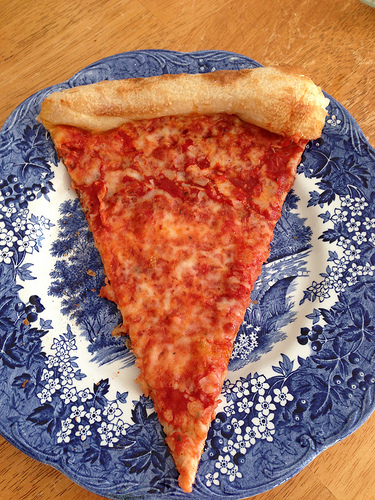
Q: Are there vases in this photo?
A: No, there are no vases.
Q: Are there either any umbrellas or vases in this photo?
A: No, there are no vases or umbrellas.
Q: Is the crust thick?
A: Yes, the crust is thick.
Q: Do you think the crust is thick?
A: Yes, the crust is thick.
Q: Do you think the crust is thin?
A: No, the crust is thick.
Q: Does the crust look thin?
A: No, the crust is thick.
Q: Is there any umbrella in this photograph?
A: No, there are no umbrellas.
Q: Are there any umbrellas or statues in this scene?
A: No, there are no umbrellas or statues.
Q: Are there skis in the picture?
A: No, there are no skis.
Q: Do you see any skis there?
A: No, there are no skis.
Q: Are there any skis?
A: No, there are no skis.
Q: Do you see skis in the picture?
A: No, there are no skis.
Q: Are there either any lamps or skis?
A: No, there are no skis or lamps.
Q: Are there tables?
A: Yes, there is a table.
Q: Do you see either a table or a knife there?
A: Yes, there is a table.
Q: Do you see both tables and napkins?
A: No, there is a table but no napkins.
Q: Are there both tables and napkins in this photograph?
A: No, there is a table but no napkins.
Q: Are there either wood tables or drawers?
A: Yes, there is a wood table.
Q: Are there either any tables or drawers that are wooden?
A: Yes, the table is wooden.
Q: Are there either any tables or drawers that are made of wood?
A: Yes, the table is made of wood.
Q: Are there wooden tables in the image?
A: Yes, there is a wood table.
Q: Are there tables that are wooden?
A: Yes, there is a table that is wooden.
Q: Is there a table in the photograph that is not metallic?
A: Yes, there is a wooden table.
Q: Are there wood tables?
A: Yes, there is a table that is made of wood.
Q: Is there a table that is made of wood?
A: Yes, there is a table that is made of wood.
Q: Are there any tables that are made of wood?
A: Yes, there is a table that is made of wood.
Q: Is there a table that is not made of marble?
A: Yes, there is a table that is made of wood.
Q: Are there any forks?
A: No, there are no forks.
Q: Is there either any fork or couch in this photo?
A: No, there are no forks or couches.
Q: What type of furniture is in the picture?
A: The furniture is a table.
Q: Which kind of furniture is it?
A: The piece of furniture is a table.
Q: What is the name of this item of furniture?
A: This is a table.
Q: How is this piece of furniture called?
A: This is a table.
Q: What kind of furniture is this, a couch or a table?
A: This is a table.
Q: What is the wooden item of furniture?
A: The piece of furniture is a table.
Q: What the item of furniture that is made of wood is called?
A: The piece of furniture is a table.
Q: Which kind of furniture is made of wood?
A: The furniture is a table.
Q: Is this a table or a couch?
A: This is a table.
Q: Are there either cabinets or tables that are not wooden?
A: No, there is a table but it is wooden.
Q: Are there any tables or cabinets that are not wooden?
A: No, there is a table but it is wooden.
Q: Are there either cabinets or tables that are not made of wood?
A: No, there is a table but it is made of wood.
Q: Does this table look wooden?
A: Yes, the table is wooden.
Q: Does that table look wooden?
A: Yes, the table is wooden.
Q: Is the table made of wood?
A: Yes, the table is made of wood.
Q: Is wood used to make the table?
A: Yes, the table is made of wood.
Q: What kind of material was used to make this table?
A: The table is made of wood.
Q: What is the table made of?
A: The table is made of wood.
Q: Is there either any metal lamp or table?
A: No, there is a table but it is wooden.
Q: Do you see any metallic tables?
A: No, there is a table but it is wooden.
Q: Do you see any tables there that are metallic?
A: No, there is a table but it is wooden.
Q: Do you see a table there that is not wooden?
A: No, there is a table but it is wooden.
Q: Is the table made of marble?
A: No, the table is made of wood.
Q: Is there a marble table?
A: No, there is a table but it is made of wood.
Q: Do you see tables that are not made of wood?
A: No, there is a table but it is made of wood.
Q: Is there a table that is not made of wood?
A: No, there is a table but it is made of wood.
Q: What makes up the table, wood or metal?
A: The table is made of wood.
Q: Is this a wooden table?
A: Yes, this is a wooden table.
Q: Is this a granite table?
A: No, this is a wooden table.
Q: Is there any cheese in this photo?
A: Yes, there is cheese.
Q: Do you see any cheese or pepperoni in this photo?
A: Yes, there is cheese.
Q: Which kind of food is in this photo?
A: The food is cheese.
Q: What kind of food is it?
A: The food is cheese.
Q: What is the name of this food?
A: This is cheese.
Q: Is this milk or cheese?
A: This is cheese.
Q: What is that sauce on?
A: The sauce is on the cheese.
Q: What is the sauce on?
A: The sauce is on the cheese.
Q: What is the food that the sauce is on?
A: The food is cheese.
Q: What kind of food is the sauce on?
A: The sauce is on the cheese.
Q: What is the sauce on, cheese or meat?
A: The sauce is on cheese.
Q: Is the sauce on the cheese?
A: Yes, the sauce is on the cheese.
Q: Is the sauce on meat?
A: No, the sauce is on the cheese.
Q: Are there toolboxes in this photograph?
A: No, there are no toolboxes.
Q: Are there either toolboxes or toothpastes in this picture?
A: No, there are no toolboxes or toothpastes.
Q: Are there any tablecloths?
A: No, there are no tablecloths.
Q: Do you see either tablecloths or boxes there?
A: No, there are no tablecloths or boxes.